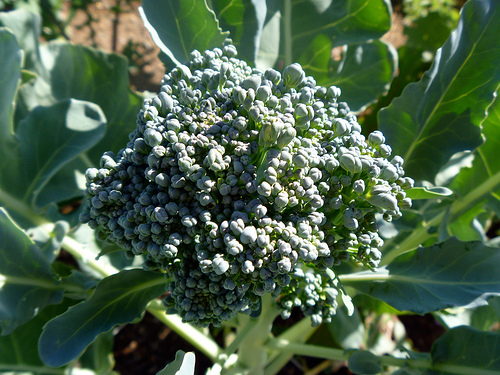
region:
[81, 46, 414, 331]
open buds of a broccoli plant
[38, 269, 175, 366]
a broccoli plant leaf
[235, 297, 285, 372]
the stalk of a broccoli plant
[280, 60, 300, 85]
a broccoli plants seedlings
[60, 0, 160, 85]
the brown dirt of a vegetable garden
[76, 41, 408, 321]
a broccoli head of loose buds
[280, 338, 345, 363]
the stem of a leaf on a broccoli plant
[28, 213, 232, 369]
a long stem of a leaf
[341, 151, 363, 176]
the swelling buds of a broccoli plant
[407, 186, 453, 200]
a new leaf on a broccoli plant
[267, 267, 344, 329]
Bunch of grapes that's bottom center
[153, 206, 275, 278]
Lower left bunch of grapes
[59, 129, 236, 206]
Bunch of grapes to the right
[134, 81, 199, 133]
Upper right bunch of grapes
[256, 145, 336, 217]
Center bunch of grapes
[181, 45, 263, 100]
Top bunch of grapes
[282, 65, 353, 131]
Top left bunch of grapes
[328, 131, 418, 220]
Middle left bunch of grapes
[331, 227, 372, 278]
Bottom left bunch of grapes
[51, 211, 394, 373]
Crate holding bunch of grapes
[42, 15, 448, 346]
broccoli florets tightly closed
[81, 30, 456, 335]
sunlight shining on green vegetable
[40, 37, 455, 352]
leaves curled around center of plant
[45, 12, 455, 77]
brown dirt in back of plant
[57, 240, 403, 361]
branches on different levels of stem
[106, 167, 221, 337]
florets on shaded side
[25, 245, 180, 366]
long and narrow leaf leaning over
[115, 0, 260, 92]
folded leaf on top of florets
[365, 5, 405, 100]
curled edges of leaves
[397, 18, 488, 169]
yellow veining throughout leaf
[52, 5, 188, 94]
brown dirt peeking from behind a broccoli plant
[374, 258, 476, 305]
sunlight reflecting on a leaf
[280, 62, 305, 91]
a fat broccoli floret poking out from the others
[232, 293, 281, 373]
a broccoli stem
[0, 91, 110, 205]
a leaf of a broccoli plant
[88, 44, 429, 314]
a small head of broccoli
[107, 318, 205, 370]
dark shadows on the dirt under the plant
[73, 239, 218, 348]
the fat stem of a broccoli leaf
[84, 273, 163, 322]
the vein of a broccoli leaf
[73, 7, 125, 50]
a different plant behind the broccoli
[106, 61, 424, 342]
a cluster of flower buds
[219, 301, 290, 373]
a thick green stem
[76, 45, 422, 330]
a young, forming broccoli head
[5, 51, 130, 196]
a few large leaves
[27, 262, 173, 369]
a healthy green leaf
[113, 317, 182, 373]
some dark, wet soil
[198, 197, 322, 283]
green globe like parts of plant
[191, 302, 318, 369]
a few stems branching out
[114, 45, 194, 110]
a shadow in the dirt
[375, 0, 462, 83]
blurry plants in background